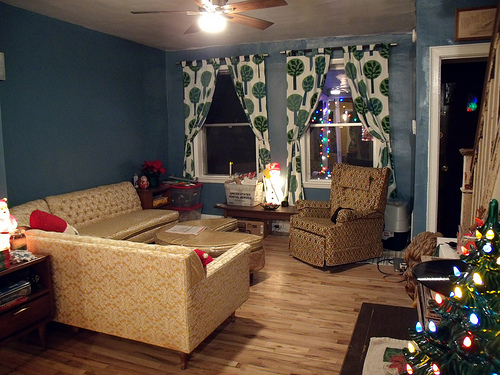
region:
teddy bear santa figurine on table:
[0, 195, 17, 250]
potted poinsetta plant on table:
[140, 157, 166, 184]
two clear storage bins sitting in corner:
[164, 179, 205, 218]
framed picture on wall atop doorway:
[456, 9, 498, 39]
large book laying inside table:
[0, 277, 35, 303]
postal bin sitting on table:
[226, 172, 263, 209]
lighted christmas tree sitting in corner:
[399, 206, 498, 371]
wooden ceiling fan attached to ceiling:
[130, 0, 283, 40]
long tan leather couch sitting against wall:
[8, 180, 189, 243]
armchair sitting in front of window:
[287, 166, 387, 265]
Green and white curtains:
[176, 50, 271, 180]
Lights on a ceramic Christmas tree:
[403, 195, 498, 373]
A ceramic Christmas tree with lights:
[403, 200, 496, 371]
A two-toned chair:
[288, 162, 390, 269]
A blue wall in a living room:
[14, 18, 167, 155]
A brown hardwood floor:
[253, 269, 354, 374]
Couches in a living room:
[2, 180, 256, 364]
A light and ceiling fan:
[127, 0, 292, 38]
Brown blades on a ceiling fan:
[125, 1, 297, 37]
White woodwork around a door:
[423, 39, 475, 234]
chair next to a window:
[271, 143, 391, 273]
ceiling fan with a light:
[131, 1, 291, 67]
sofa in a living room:
[82, 231, 297, 356]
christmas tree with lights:
[447, 237, 493, 372]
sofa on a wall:
[82, 186, 150, 226]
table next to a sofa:
[180, 211, 251, 239]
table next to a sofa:
[21, 250, 57, 320]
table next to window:
[217, 198, 283, 213]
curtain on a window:
[178, 45, 265, 161]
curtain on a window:
[285, 35, 390, 138]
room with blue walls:
[0, 0, 430, 242]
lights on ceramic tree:
[404, 203, 499, 372]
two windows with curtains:
[181, 44, 393, 185]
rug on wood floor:
[336, 299, 417, 374]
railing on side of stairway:
[460, 37, 499, 238]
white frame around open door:
[426, 41, 492, 235]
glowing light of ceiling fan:
[129, 9, 272, 32]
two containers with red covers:
[167, 178, 202, 223]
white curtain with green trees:
[285, 42, 390, 209]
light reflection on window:
[308, 68, 371, 180]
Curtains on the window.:
[178, 53, 272, 183]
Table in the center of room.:
[173, 205, 274, 250]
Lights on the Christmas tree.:
[454, 212, 499, 349]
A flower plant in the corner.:
[136, 139, 163, 189]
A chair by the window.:
[285, 159, 389, 274]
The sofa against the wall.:
[36, 192, 181, 237]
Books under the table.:
[1, 274, 49, 302]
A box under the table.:
[233, 211, 270, 236]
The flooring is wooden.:
[243, 280, 327, 370]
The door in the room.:
[436, 77, 477, 222]